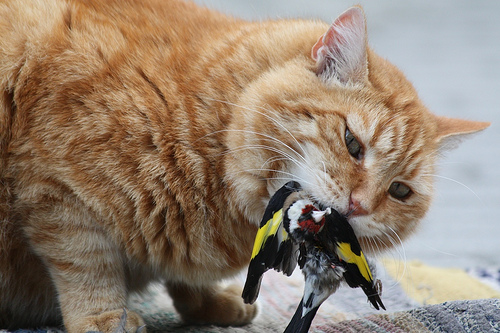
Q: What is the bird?
A: Black and yellow.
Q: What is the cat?
A: Orange and white.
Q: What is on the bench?
A: The orange cat.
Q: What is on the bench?
A: The orange tabby cat.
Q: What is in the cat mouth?
A: The bird.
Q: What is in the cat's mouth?
A: The dead bird.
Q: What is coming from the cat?
A: Several whiskers.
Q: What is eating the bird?
A: The cat.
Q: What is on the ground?
A: The fat cat leg.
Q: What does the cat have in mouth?
A: Bird.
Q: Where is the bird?
A: Cat mouth.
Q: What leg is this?
A: Front leg.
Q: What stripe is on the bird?
A: Yellow.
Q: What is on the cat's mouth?
A: Whiskers.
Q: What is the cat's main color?
A: Orange.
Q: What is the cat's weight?
A: Overweight.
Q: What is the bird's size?
A: Small.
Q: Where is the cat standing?
A: On the asphalt.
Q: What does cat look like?
A: Orange striped.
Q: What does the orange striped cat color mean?
A: Tabby.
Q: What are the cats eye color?
A: Green.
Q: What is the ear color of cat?
A: Pink.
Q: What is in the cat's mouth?
A: A bird.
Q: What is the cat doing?
A: Eating the bird.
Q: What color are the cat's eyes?
A: Green.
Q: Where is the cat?
A: On the rug.